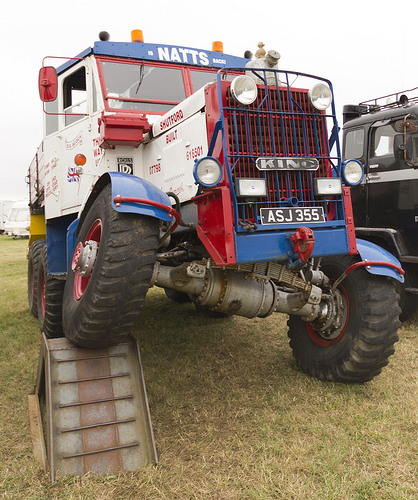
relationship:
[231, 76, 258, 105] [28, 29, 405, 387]
headlight on truck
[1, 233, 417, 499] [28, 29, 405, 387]
grass under truck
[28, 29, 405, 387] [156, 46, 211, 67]
truck has writing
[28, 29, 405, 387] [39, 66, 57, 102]
truck has a side mirror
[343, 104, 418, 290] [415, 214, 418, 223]
car has writing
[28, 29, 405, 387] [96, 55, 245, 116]
truck has a windshield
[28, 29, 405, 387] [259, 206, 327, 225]
truck has a license plate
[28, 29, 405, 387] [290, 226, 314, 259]
truck has a clamp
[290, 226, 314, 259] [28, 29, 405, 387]
clamp on truck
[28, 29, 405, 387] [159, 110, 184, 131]
truck has a sticker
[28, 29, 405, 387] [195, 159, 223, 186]
truck has a headlight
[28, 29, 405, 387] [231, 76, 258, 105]
truck has a headlight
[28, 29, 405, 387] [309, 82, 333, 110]
truck has a headlight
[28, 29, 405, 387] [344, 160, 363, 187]
truck has a headlight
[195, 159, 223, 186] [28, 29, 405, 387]
headlight on truck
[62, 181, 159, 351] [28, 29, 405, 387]
tire on truck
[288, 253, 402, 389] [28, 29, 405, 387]
tire attached to truck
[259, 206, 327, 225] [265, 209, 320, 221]
tag has letters